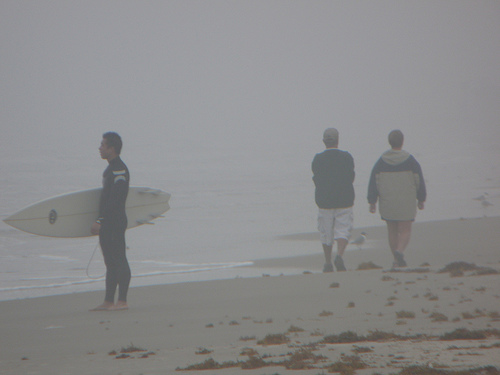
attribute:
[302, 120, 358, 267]
man — walking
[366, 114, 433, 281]
woman — walking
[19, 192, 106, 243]
board — white, whtie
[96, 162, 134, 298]
wetsuit — black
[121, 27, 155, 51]
sky — foggy